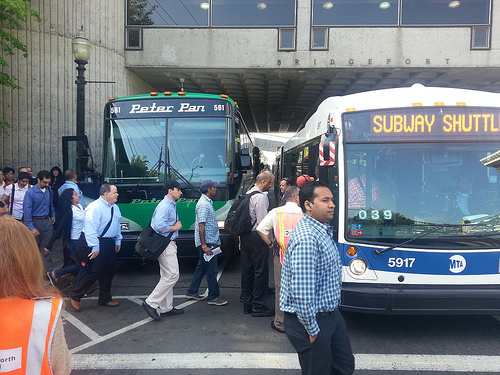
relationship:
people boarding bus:
[2, 147, 314, 297] [98, 75, 498, 318]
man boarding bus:
[133, 179, 185, 320] [265, 86, 496, 322]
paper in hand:
[201, 247, 227, 264] [191, 203, 215, 255]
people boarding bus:
[46, 184, 264, 285] [76, 100, 256, 221]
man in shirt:
[279, 180, 354, 373] [277, 212, 342, 335]